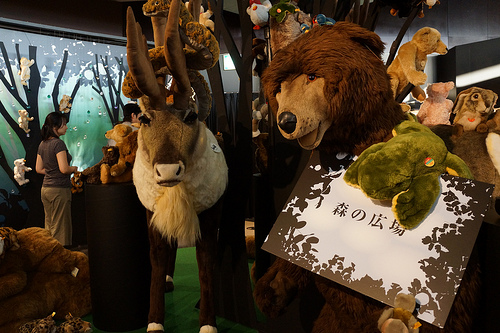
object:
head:
[257, 19, 392, 153]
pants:
[40, 186, 74, 248]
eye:
[302, 73, 321, 85]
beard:
[150, 183, 203, 248]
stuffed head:
[125, 0, 229, 189]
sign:
[258, 147, 495, 330]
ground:
[89, 244, 306, 332]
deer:
[123, 0, 234, 332]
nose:
[275, 108, 303, 134]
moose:
[124, 0, 231, 332]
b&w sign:
[258, 141, 496, 329]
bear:
[251, 19, 484, 332]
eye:
[272, 85, 281, 95]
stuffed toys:
[342, 118, 477, 232]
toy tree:
[197, 0, 431, 331]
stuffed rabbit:
[450, 85, 500, 132]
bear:
[384, 25, 452, 112]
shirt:
[37, 135, 80, 189]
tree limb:
[0, 39, 22, 99]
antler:
[162, 0, 196, 108]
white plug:
[201, 158, 223, 187]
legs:
[141, 210, 172, 324]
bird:
[244, 0, 274, 31]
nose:
[354, 165, 401, 203]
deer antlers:
[123, 4, 168, 108]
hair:
[147, 180, 205, 246]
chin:
[156, 182, 183, 187]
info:
[332, 201, 408, 238]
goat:
[124, 0, 237, 332]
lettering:
[329, 198, 417, 238]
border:
[438, 183, 500, 330]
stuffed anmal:
[16, 108, 34, 134]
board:
[257, 137, 495, 328]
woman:
[32, 110, 80, 254]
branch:
[0, 100, 29, 151]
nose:
[152, 162, 185, 182]